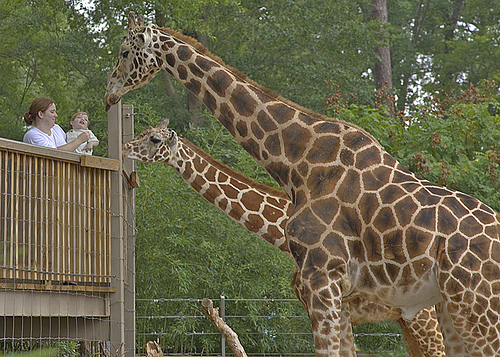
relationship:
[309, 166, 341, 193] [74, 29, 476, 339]
spots on giraffe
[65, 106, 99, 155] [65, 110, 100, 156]
hair on baby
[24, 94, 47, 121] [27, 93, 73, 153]
hair of woman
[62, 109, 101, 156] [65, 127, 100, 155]
baby wearing shirt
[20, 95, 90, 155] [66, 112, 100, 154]
mother holding baby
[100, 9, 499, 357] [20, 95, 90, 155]
giraffe looking at mother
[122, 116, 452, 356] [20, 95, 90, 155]
giraffe looking at mother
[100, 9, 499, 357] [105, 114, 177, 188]
giraffe trying to eat food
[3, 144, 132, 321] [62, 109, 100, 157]
fence in front of baby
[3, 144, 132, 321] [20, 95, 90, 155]
fence in front of mother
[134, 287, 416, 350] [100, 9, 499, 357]
fence behind giraffe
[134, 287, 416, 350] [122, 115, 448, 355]
fence behind giraffe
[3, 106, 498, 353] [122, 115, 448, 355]
pen enclosing giraffe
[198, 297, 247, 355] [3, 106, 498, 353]
tree branch in pen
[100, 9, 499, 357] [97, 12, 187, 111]
giraffe has head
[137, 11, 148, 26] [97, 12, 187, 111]
horn on head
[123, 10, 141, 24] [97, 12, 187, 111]
horn on head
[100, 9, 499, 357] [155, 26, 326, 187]
giraffe has neck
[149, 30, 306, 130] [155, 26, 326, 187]
hair on neck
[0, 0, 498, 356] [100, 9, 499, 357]
tree behind giraffe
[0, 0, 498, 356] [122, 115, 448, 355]
tree behind giraffe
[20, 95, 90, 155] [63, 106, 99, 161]
mother holding child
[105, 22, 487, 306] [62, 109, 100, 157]
giraffe looking at baby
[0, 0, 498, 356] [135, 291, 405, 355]
tree standing behind fence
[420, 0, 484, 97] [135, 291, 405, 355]
tree standing behind fence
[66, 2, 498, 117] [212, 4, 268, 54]
sky seen behind tree branch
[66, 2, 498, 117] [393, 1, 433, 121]
sky seen behind tree branch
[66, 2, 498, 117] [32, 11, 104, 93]
sky seen behind tree branch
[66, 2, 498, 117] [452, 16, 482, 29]
sky seen behind tree branch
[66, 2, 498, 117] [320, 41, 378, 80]
sky seen behind tree branch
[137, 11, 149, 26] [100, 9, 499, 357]
horn growing on giraffe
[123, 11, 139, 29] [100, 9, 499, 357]
horn growing on giraffe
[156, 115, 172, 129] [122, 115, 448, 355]
horn growing on giraffe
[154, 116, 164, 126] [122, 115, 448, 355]
horn growing on giraffe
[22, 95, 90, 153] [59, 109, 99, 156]
mother holding child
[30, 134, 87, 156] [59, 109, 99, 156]
arm holding child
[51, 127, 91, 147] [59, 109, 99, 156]
arm holding child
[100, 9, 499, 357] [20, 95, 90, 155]
giraffe standing near mother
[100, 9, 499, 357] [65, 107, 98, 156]
giraffe standing near person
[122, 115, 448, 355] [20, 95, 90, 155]
giraffe standing near mother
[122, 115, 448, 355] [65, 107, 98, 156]
giraffe standing near person